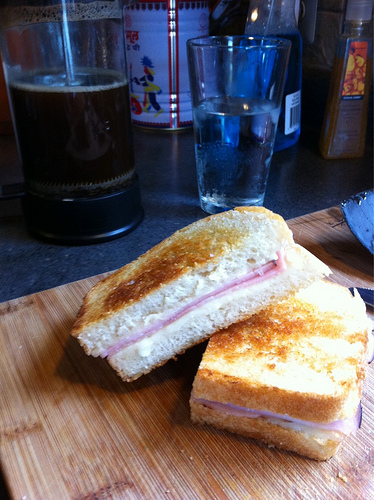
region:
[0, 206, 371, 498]
A sandwich is on the board.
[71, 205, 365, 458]
The sandwich is cut in two.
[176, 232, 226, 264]
The sandwich has been toasted.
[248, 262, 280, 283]
The sandwich contains ham.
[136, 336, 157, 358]
The sandwich contains melted cheese.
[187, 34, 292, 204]
A glass is on the table.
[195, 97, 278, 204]
The glass contains water.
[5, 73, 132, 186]
A dark beverage is in the glass.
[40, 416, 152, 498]
The board is wooden.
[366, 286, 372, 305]
A knife is next to the sandwich.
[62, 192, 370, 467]
A toasted sliced sandwich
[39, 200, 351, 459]
a simple sandwich cut in half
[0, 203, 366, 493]
sandwich is sitting on a cutting board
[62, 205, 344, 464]
bread is toasted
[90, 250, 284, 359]
deli meat is inside of the sandwich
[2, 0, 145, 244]
a french press with coffee in it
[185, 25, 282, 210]
a glass of water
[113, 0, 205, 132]
a white tin can in the background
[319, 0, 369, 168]
a triange shaped container with an orange substance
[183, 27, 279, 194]
this is a glass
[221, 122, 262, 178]
the glass is shinny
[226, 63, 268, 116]
the glass is transparent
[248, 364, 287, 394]
the sandwich is brown in color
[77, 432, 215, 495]
this is a table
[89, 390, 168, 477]
the table is brown i color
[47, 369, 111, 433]
the table is wooden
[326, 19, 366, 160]
this is a bottle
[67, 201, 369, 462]
One sandwich is on top of the other.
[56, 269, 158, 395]
The bread is touching the cutting board.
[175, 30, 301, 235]
The glass of water is on top of the counter.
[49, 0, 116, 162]
The spoon is inside of the coffee.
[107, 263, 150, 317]
The bread is toasted.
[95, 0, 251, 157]
The soda can is behind the coffee and water.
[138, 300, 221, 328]
The ham is between the two breads.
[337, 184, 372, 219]
Water droplets are on the spatula.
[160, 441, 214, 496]
Crumbs are on the cutting board.